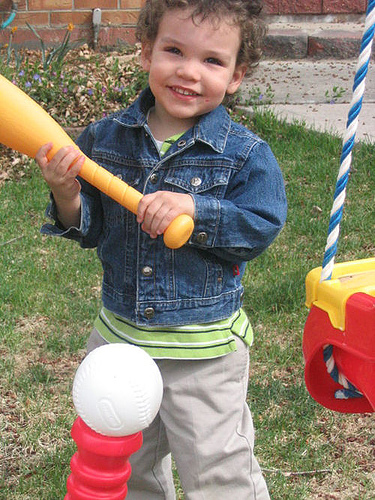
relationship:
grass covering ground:
[287, 137, 372, 265] [1, 45, 373, 498]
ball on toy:
[74, 341, 164, 441] [57, 416, 141, 499]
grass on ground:
[0, 117, 375, 500] [1, 45, 373, 498]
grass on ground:
[0, 117, 375, 500] [0, 118, 368, 492]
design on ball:
[131, 342, 151, 429] [74, 341, 164, 441]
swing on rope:
[301, 255, 373, 413] [322, 0, 373, 398]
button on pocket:
[186, 173, 205, 188] [165, 160, 232, 194]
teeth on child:
[168, 83, 204, 101] [2, 3, 299, 498]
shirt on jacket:
[87, 299, 260, 360] [43, 87, 285, 327]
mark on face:
[205, 99, 210, 102] [148, 3, 242, 118]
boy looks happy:
[38, 5, 286, 500] [135, 0, 270, 118]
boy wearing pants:
[38, 5, 286, 500] [145, 354, 276, 499]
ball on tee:
[70, 340, 165, 438] [53, 419, 145, 498]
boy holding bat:
[38, 0, 294, 495] [2, 62, 193, 253]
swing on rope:
[301, 255, 373, 413] [317, 26, 359, 282]